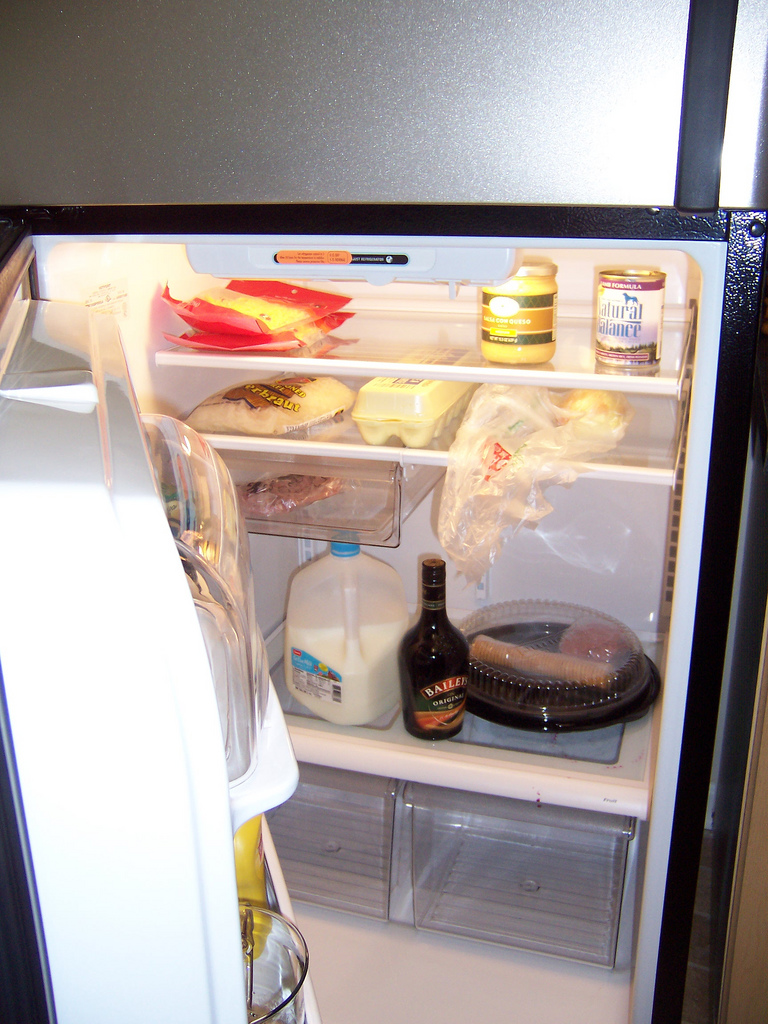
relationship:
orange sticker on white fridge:
[271, 247, 357, 273] [2, 235, 709, 1018]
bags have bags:
[148, 274, 368, 356] [160, 279, 357, 351]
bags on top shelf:
[148, 274, 368, 356] [155, 306, 689, 402]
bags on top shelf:
[160, 279, 357, 351] [155, 306, 689, 402]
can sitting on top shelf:
[584, 260, 676, 378] [155, 306, 689, 402]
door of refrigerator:
[8, 21, 763, 1020] [4, 246, 326, 1020]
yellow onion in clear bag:
[556, 388, 624, 436] [435, 377, 622, 565]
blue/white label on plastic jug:
[285, 643, 345, 708] [281, 536, 405, 725]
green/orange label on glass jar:
[478, 290, 553, 348] [479, 259, 559, 362]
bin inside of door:
[380, 787, 643, 988] [0, 0, 768, 1023]